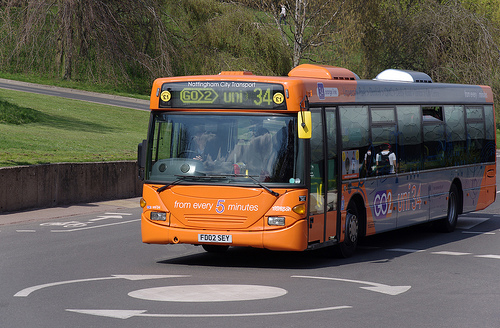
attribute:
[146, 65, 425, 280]
bus — commuter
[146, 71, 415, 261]
bus — orange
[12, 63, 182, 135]
road — sloping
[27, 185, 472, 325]
road — marked, tarmacked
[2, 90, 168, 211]
grass — green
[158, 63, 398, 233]
bus — riding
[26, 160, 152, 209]
wall — concrete, retaining